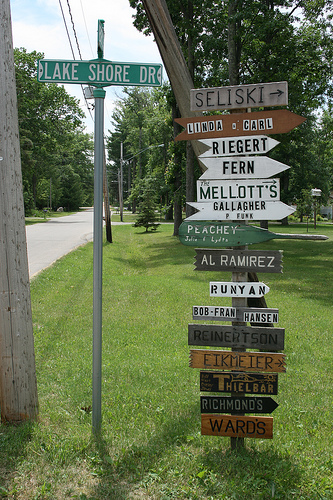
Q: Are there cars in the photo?
A: No, there are no cars.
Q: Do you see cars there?
A: No, there are no cars.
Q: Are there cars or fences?
A: No, there are no cars or fences.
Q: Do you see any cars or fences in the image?
A: No, there are no cars or fences.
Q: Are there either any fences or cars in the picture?
A: No, there are no cars or fences.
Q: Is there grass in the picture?
A: Yes, there is grass.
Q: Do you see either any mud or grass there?
A: Yes, there is grass.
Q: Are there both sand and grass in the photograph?
A: No, there is grass but no sand.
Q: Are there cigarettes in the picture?
A: No, there are no cigarettes.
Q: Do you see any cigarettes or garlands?
A: No, there are no cigarettes or garlands.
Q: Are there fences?
A: No, there are no fences.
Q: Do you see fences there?
A: No, there are no fences.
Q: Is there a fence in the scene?
A: No, there are no fences.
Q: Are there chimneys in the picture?
A: No, there are no chimneys.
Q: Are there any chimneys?
A: No, there are no chimneys.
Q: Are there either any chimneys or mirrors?
A: No, there are no chimneys or mirrors.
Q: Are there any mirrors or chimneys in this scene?
A: No, there are no chimneys or mirrors.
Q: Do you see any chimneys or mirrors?
A: No, there are no chimneys or mirrors.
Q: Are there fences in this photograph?
A: No, there are no fences.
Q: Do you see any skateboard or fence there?
A: No, there are no fences or skateboards.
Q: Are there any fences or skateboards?
A: No, there are no fences or skateboards.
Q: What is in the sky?
A: The wires are in the sky.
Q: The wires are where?
A: The wires are in the sky.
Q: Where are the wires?
A: The wires are in the sky.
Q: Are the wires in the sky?
A: Yes, the wires are in the sky.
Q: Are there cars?
A: No, there are no cars.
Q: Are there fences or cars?
A: No, there are no cars or fences.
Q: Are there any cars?
A: No, there are no cars.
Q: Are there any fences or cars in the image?
A: No, there are no cars or fences.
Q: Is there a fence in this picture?
A: No, there are no fences.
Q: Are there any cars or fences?
A: No, there are no fences or cars.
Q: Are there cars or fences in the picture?
A: No, there are no fences or cars.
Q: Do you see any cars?
A: No, there are no cars.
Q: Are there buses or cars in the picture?
A: No, there are no cars or buses.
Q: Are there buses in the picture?
A: No, there are no buses.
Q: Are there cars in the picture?
A: No, there are no cars.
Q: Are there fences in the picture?
A: No, there are no fences.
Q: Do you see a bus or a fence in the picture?
A: No, there are no fences or buses.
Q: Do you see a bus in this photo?
A: No, there are no buses.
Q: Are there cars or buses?
A: No, there are no buses or cars.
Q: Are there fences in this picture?
A: No, there are no fences.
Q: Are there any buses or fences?
A: No, there are no fences or buses.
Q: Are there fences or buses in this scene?
A: No, there are no fences or buses.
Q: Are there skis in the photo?
A: No, there are no skis.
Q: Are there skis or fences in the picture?
A: No, there are no skis or fences.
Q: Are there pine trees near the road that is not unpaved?
A: Yes, there is a pine tree near the road.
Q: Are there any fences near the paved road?
A: No, there is a pine tree near the road.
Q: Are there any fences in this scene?
A: No, there are no fences.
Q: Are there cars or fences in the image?
A: No, there are no fences or cars.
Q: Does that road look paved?
A: Yes, the road is paved.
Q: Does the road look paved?
A: Yes, the road is paved.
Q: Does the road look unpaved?
A: No, the road is paved.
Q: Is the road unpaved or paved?
A: The road is paved.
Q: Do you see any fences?
A: No, there are no fences.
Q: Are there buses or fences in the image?
A: No, there are no fences or buses.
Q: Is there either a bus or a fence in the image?
A: No, there are no fences or buses.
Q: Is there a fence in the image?
A: No, there are no fences.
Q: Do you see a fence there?
A: No, there are no fences.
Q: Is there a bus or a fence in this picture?
A: No, there are no fences or buses.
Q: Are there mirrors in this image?
A: No, there are no mirrors.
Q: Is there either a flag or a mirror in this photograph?
A: No, there are no mirrors or flags.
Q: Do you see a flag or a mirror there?
A: No, there are no mirrors or flags.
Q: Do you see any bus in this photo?
A: No, there are no buses.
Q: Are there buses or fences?
A: No, there are no buses or fences.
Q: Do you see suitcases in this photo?
A: No, there are no suitcases.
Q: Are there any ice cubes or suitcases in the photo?
A: No, there are no suitcases or ice cubes.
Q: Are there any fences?
A: No, there are no fences.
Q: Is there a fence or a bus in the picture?
A: No, there are no fences or buses.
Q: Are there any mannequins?
A: No, there are no mannequins.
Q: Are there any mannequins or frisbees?
A: No, there are no mannequins or frisbees.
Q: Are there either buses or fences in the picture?
A: No, there are no fences or buses.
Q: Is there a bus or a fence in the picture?
A: No, there are no fences or buses.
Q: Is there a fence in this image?
A: No, there are no fences.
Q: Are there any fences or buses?
A: No, there are no fences or buses.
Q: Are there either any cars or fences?
A: No, there are no fences or cars.